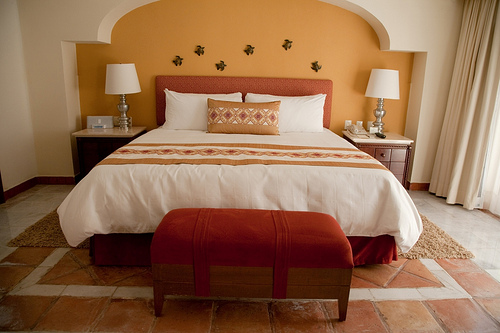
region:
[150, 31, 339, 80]
Decorative birds on an orange background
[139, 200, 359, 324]
plush and richly red ottoman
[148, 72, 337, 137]
Orange fabric headboad with white and orange pillows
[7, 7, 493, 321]
Warmly colored and well decorated bedroom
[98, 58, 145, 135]
Silver table lamp with an ivory shade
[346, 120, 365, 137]
A white corded telephone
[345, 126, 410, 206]
dark hardwood nightstand with a white surface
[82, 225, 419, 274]
A richly red bedskirt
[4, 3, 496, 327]
Sunlight is filtering into the room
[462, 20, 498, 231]
The curtains are offwhite and the sheers are ivory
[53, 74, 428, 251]
big white doubled bed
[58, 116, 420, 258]
sheets are orange and white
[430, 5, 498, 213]
white curtains hanging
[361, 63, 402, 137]
small white and metal lamp in the right side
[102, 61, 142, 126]
small white and metal lamp in the left side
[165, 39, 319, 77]
six decorative stars in yellow wall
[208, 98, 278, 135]
orange pillow in the center of bed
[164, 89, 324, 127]
two white pillows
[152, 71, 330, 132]
orange tuft of bed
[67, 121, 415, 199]
two nightstands in both sides of bed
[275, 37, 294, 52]
a turtle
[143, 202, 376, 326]
a fabric covered seat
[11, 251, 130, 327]
brown and white tiles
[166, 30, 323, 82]
a group of decor turtles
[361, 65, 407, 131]
a silver and white lamp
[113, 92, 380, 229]
a white bed spread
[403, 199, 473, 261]
a fuzzy rug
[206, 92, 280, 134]
a deoritive designer pillow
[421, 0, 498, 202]
long wite fabric curtains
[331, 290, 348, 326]
the wooden leg of a bench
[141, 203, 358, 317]
maroon and wooden bench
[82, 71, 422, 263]
bed with a white and brown bedspread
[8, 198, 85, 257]
brown carpet under the bed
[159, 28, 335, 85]
small turtles on the wall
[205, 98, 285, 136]
brown pillow with designs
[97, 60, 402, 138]
pair of silver lamps with white shades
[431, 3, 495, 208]
long white curtains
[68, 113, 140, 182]
wooden bedside table with a white top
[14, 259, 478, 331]
white and brown tiled floor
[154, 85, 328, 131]
pair of white pillows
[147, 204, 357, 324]
a red and brown bench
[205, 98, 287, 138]
a long pillow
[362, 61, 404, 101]
a white lampshade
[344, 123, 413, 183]
a brown and white table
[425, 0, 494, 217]
part of a white window curtain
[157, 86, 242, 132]
a long white pillow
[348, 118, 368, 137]
a white telephone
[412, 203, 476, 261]
part of a brown rug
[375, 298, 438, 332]
a piece of floor tile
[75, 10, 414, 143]
a brown wall